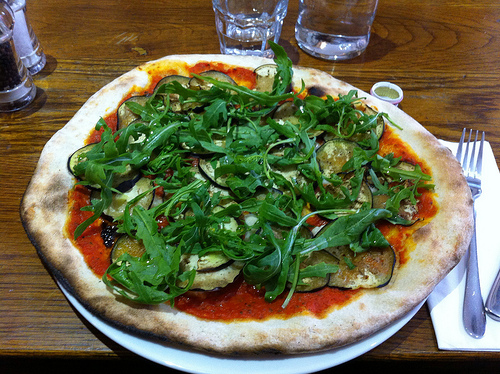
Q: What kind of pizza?
A: Vegetarian.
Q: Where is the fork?
A: On the napkin.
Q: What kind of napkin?
A: Folded.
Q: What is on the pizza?
A: Greens.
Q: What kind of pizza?
A: Vegetables.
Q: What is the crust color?
A: Brown.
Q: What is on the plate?
A: A pizza crust.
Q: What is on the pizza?
A: Leafy vegetables.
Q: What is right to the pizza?
A: A fork.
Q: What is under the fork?
A: A napkin.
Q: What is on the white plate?
A: A pizza.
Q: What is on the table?
A: A white plate.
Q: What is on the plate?
A: A pizza.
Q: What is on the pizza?
A: Basil.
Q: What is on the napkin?
A: A fork.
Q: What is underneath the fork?
A: A white napkin.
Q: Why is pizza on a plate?
A: To be eaten.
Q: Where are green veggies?
A: On the pizza.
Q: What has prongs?
A: A fork.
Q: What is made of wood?
A: The table.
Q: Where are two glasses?
A: On the table.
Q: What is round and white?
A: Plate.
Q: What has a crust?
A: Pizza pie.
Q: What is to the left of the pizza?
A: Salt and pepper shakers.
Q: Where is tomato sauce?
A: On the pizza.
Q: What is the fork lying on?
A: Napkin.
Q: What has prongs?
A: Fork.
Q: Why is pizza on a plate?
A: To be eaten.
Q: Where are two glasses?
A: On table.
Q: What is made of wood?
A: The table.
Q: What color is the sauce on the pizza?
A: Red.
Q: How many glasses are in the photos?
A: Two.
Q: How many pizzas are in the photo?
A: One.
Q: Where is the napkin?
A: The right of the pizza.